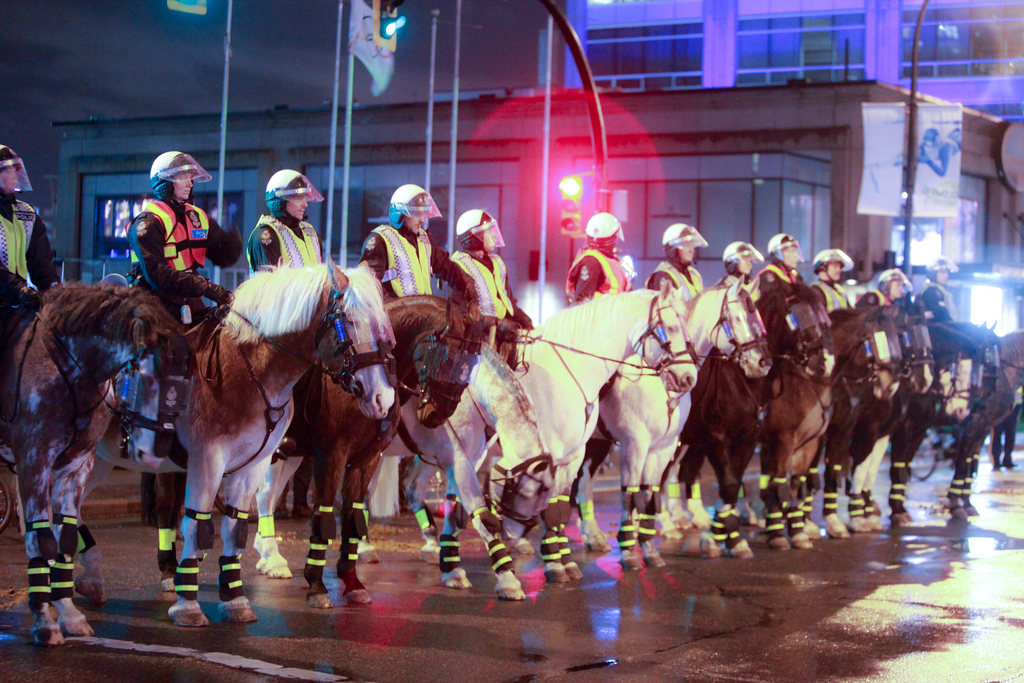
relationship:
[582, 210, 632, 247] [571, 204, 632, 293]
head of person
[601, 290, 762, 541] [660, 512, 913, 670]
horse on road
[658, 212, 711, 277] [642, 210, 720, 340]
person has head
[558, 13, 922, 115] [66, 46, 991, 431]
windows on building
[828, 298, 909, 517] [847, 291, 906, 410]
horse has head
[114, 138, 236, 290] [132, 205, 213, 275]
person wears vest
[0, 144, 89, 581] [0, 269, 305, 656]
person sitting on top of horse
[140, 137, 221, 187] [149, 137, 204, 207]
helmet on head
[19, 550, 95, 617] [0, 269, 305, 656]
strip on horse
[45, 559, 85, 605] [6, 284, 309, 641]
strip on horse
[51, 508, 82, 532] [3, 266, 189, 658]
strip on horse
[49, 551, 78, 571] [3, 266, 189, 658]
strip on horse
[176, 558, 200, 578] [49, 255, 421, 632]
strip on horse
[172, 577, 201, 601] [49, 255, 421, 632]
strip on horse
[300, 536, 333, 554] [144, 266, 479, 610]
strip on horse